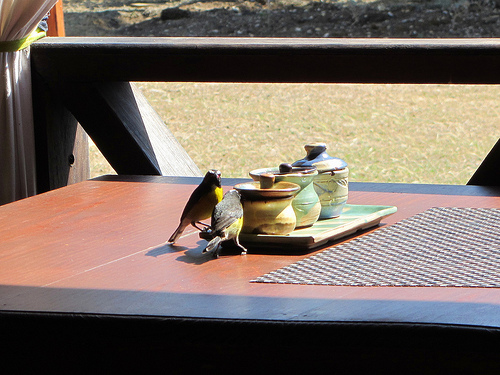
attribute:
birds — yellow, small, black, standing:
[159, 172, 256, 249]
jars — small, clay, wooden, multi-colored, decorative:
[240, 137, 356, 244]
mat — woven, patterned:
[239, 195, 496, 289]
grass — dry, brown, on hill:
[238, 88, 342, 120]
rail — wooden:
[154, 16, 436, 91]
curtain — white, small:
[5, 44, 43, 208]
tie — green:
[0, 5, 41, 63]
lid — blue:
[293, 141, 338, 173]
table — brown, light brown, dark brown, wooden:
[7, 175, 155, 259]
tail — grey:
[195, 225, 238, 270]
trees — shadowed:
[158, 21, 496, 43]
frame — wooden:
[47, 5, 65, 39]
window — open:
[46, 6, 73, 37]